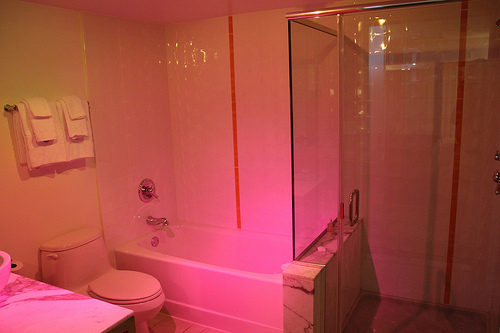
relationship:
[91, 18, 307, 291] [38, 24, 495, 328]
shower in bathroom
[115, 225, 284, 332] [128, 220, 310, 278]
bath tub next to bathtub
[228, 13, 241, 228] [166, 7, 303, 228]
line in bathtub wall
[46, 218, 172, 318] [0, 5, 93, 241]
toilet against wall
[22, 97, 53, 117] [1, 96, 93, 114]
wash cloth on rack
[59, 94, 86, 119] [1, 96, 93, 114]
wash cloth on rack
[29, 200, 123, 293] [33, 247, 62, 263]
tank has handle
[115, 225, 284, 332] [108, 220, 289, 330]
bath tub in bathroom